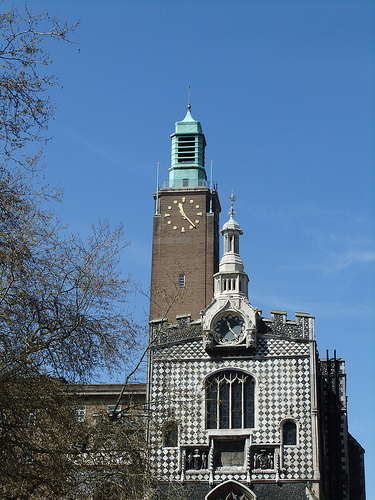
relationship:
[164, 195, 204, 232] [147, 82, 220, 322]
clock on building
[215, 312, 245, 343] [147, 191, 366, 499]
clock on building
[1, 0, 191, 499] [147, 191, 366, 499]
branches next to building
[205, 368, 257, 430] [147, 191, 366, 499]
window on building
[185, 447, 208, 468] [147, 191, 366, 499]
statues on building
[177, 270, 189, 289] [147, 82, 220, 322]
window on building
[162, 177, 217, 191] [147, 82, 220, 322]
safety rail on building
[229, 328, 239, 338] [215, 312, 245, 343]
hand on clock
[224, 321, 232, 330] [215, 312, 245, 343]
hand on clock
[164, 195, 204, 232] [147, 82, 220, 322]
clock near top of building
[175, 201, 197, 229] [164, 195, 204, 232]
hands on clock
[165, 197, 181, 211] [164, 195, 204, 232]
dots on clock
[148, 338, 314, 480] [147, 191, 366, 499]
wall on building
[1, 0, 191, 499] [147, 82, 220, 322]
branches near building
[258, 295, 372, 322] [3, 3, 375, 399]
cloud in sky